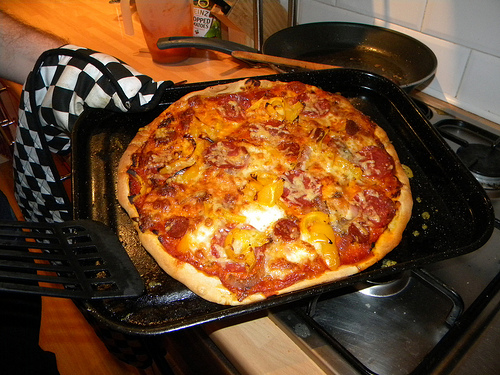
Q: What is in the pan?
A: Pizza.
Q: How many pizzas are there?
A: One.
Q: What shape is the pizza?
A: Circle.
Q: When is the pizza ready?
A: Now.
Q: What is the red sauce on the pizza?
A: Tomato.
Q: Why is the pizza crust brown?
A: It was cooked.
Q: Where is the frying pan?
A: Stove.